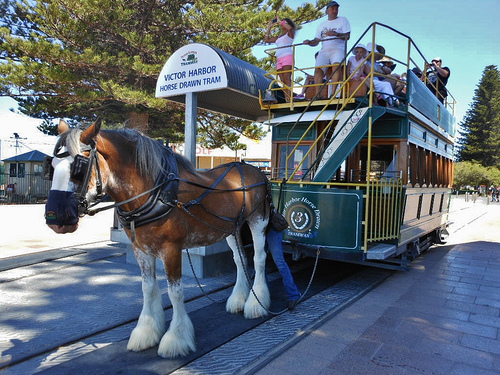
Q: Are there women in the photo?
A: Yes, there is a woman.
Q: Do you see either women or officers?
A: Yes, there is a woman.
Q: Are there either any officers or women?
A: Yes, there is a woman.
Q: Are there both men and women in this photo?
A: Yes, there are both a woman and a man.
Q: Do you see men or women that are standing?
A: Yes, the woman is standing.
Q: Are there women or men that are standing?
A: Yes, the woman is standing.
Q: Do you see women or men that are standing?
A: Yes, the woman is standing.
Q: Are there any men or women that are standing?
A: Yes, the woman is standing.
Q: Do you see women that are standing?
A: Yes, there is a woman that is standing.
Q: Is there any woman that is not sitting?
A: Yes, there is a woman that is standing.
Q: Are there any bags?
A: No, there are no bags.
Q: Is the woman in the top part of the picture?
A: Yes, the woman is in the top of the image.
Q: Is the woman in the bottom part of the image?
A: No, the woman is in the top of the image.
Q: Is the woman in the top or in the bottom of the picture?
A: The woman is in the top of the image.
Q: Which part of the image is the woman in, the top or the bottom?
A: The woman is in the top of the image.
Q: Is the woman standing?
A: Yes, the woman is standing.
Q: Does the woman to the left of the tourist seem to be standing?
A: Yes, the woman is standing.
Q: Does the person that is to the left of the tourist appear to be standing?
A: Yes, the woman is standing.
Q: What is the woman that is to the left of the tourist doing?
A: The woman is standing.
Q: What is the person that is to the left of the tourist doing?
A: The woman is standing.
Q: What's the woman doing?
A: The woman is standing.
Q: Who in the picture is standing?
A: The woman is standing.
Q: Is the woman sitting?
A: No, the woman is standing.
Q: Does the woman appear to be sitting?
A: No, the woman is standing.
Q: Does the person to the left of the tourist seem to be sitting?
A: No, the woman is standing.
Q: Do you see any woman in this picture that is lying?
A: No, there is a woman but she is standing.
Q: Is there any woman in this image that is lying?
A: No, there is a woman but she is standing.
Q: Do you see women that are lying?
A: No, there is a woman but she is standing.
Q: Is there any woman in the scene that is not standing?
A: No, there is a woman but she is standing.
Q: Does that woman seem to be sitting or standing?
A: The woman is standing.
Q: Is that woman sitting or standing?
A: The woman is standing.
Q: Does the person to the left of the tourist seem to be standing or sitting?
A: The woman is standing.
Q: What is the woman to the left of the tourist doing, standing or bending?
A: The woman is standing.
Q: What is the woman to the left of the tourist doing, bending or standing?
A: The woman is standing.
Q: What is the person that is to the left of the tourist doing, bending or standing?
A: The woman is standing.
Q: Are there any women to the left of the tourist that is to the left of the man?
A: Yes, there is a woman to the left of the tourist.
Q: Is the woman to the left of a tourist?
A: Yes, the woman is to the left of a tourist.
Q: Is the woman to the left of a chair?
A: No, the woman is to the left of a tourist.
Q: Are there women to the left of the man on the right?
A: Yes, there is a woman to the left of the man.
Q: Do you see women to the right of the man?
A: No, the woman is to the left of the man.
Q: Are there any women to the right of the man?
A: No, the woman is to the left of the man.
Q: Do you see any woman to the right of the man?
A: No, the woman is to the left of the man.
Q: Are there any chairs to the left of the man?
A: No, there is a woman to the left of the man.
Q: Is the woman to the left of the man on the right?
A: Yes, the woman is to the left of the man.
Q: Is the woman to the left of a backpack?
A: No, the woman is to the left of the man.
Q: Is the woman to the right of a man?
A: No, the woman is to the left of a man.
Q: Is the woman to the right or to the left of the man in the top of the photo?
A: The woman is to the left of the man.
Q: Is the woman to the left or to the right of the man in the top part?
A: The woman is to the left of the man.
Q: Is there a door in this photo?
A: Yes, there is a door.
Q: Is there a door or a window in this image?
A: Yes, there is a door.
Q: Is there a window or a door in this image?
A: Yes, there is a door.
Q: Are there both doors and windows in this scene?
A: Yes, there are both a door and a window.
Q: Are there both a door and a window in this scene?
A: Yes, there are both a door and a window.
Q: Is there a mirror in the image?
A: No, there are no mirrors.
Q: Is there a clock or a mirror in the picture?
A: No, there are no mirrors or clocks.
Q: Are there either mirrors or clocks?
A: No, there are no mirrors or clocks.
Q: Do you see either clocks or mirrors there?
A: No, there are no mirrors or clocks.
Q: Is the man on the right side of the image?
A: Yes, the man is on the right of the image.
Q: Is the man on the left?
A: No, the man is on the right of the image.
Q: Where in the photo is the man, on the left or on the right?
A: The man is on the right of the image.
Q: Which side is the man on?
A: The man is on the right of the image.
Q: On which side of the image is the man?
A: The man is on the right of the image.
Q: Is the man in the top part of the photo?
A: Yes, the man is in the top of the image.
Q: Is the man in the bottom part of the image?
A: No, the man is in the top of the image.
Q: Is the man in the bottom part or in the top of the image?
A: The man is in the top of the image.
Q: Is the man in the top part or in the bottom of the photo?
A: The man is in the top of the image.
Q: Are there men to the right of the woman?
A: Yes, there is a man to the right of the woman.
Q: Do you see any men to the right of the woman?
A: Yes, there is a man to the right of the woman.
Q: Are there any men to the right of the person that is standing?
A: Yes, there is a man to the right of the woman.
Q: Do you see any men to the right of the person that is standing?
A: Yes, there is a man to the right of the woman.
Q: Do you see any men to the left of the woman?
A: No, the man is to the right of the woman.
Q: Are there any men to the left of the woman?
A: No, the man is to the right of the woman.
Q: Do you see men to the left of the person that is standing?
A: No, the man is to the right of the woman.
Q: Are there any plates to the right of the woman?
A: No, there is a man to the right of the woman.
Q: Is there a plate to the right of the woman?
A: No, there is a man to the right of the woman.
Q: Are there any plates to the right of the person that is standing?
A: No, there is a man to the right of the woman.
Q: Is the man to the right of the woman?
A: Yes, the man is to the right of the woman.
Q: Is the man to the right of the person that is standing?
A: Yes, the man is to the right of the woman.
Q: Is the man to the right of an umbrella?
A: No, the man is to the right of the woman.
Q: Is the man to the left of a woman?
A: No, the man is to the right of a woman.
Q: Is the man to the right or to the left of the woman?
A: The man is to the right of the woman.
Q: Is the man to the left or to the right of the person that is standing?
A: The man is to the right of the woman.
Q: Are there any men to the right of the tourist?
A: Yes, there is a man to the right of the tourist.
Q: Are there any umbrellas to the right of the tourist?
A: No, there is a man to the right of the tourist.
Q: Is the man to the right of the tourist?
A: Yes, the man is to the right of the tourist.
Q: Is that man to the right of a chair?
A: No, the man is to the right of the tourist.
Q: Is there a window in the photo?
A: Yes, there are windows.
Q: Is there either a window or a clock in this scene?
A: Yes, there are windows.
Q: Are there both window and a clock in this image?
A: No, there are windows but no clocks.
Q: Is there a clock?
A: No, there are no clocks.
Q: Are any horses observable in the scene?
A: Yes, there is a horse.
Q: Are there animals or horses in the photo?
A: Yes, there is a horse.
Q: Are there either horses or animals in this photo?
A: Yes, there is a horse.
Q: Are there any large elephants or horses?
A: Yes, there is a large horse.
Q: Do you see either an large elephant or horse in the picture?
A: Yes, there is a large horse.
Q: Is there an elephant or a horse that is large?
A: Yes, the horse is large.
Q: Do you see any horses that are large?
A: Yes, there is a large horse.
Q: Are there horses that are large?
A: Yes, there is a horse that is large.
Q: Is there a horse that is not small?
A: Yes, there is a large horse.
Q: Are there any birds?
A: No, there are no birds.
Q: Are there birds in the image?
A: No, there are no birds.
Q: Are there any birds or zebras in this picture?
A: No, there are no birds or zebras.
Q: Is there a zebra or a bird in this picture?
A: No, there are no birds or zebras.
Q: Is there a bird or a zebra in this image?
A: No, there are no birds or zebras.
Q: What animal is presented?
A: The animal is a horse.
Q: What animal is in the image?
A: The animal is a horse.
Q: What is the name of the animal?
A: The animal is a horse.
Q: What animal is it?
A: The animal is a horse.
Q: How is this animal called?
A: This is a horse.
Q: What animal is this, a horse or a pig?
A: This is a horse.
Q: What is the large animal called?
A: The animal is a horse.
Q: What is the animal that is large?
A: The animal is a horse.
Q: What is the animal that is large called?
A: The animal is a horse.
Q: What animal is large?
A: The animal is a horse.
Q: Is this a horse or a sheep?
A: This is a horse.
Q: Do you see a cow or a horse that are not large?
A: No, there is a horse but it is large.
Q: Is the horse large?
A: Yes, the horse is large.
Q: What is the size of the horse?
A: The horse is large.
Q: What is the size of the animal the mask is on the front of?
A: The horse is large.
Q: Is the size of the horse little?
A: No, the horse is large.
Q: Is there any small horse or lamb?
A: No, there is a horse but it is large.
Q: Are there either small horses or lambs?
A: No, there is a horse but it is large.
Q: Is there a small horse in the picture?
A: No, there is a horse but it is large.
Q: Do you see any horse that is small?
A: No, there is a horse but it is large.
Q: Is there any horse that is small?
A: No, there is a horse but it is large.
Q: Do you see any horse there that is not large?
A: No, there is a horse but it is large.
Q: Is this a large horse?
A: Yes, this is a large horse.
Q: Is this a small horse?
A: No, this is a large horse.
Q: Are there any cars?
A: No, there are no cars.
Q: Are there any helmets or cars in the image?
A: No, there are no cars or helmets.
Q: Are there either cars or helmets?
A: No, there are no cars or helmets.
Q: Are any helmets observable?
A: No, there are no helmets.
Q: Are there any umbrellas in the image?
A: No, there are no umbrellas.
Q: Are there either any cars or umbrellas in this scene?
A: No, there are no umbrellas or cars.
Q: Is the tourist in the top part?
A: Yes, the tourist is in the top of the image.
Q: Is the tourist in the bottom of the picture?
A: No, the tourist is in the top of the image.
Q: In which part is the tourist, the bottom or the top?
A: The tourist is in the top of the image.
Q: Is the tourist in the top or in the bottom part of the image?
A: The tourist is in the top of the image.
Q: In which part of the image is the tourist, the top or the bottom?
A: The tourist is in the top of the image.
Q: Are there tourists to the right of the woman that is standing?
A: Yes, there is a tourist to the right of the woman.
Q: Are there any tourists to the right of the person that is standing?
A: Yes, there is a tourist to the right of the woman.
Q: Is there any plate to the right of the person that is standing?
A: No, there is a tourist to the right of the woman.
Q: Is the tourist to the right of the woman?
A: Yes, the tourist is to the right of the woman.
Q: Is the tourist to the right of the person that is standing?
A: Yes, the tourist is to the right of the woman.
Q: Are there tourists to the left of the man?
A: Yes, there is a tourist to the left of the man.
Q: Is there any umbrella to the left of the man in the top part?
A: No, there is a tourist to the left of the man.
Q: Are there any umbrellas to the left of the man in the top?
A: No, there is a tourist to the left of the man.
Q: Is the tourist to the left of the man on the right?
A: Yes, the tourist is to the left of the man.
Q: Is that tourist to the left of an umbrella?
A: No, the tourist is to the left of the man.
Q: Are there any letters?
A: Yes, there are letters.